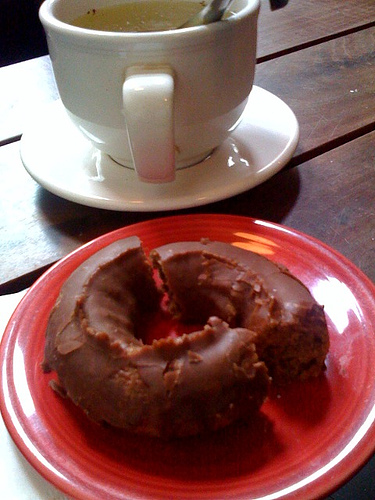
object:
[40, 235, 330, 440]
donut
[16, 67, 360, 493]
foreground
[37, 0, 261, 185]
cup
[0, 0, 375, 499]
table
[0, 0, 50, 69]
background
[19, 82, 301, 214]
plate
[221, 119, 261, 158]
light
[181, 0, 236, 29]
utensil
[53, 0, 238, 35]
soup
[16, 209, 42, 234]
glare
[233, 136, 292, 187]
reflection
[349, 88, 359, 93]
dirt